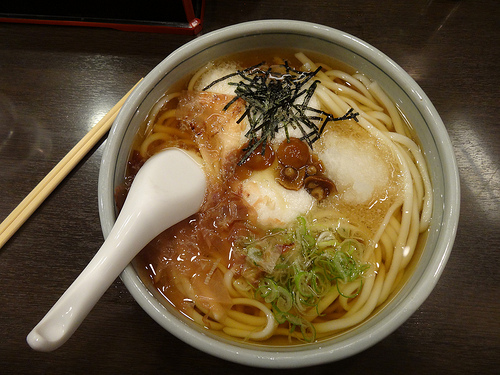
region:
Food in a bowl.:
[77, 21, 468, 371]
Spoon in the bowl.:
[41, 113, 276, 358]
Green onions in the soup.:
[215, 139, 405, 334]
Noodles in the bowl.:
[240, 57, 440, 274]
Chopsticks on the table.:
[22, 71, 212, 275]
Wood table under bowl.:
[39, 52, 432, 370]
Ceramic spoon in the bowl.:
[16, 110, 366, 371]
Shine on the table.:
[54, 58, 164, 189]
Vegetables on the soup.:
[200, 57, 365, 194]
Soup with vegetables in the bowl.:
[75, 57, 475, 302]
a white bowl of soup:
[84, 13, 479, 372]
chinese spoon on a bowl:
[9, 130, 214, 357]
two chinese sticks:
[10, 55, 140, 251]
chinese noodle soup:
[115, 47, 435, 340]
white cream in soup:
[232, 169, 308, 230]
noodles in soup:
[328, 65, 430, 280]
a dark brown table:
[0, 0, 499, 374]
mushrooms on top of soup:
[230, 124, 336, 209]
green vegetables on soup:
[211, 205, 374, 332]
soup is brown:
[111, 45, 439, 350]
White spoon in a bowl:
[128, 138, 222, 235]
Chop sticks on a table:
[1, 77, 131, 252]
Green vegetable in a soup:
[251, 233, 359, 316]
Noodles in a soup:
[373, 209, 425, 291]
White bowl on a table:
[98, 25, 457, 370]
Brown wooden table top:
[428, 310, 497, 374]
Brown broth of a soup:
[240, 47, 290, 67]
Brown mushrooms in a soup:
[276, 135, 311, 165]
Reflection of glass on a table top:
[3, 80, 60, 187]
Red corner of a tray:
[178, 0, 208, 32]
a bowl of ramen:
[187, 102, 418, 349]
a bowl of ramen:
[240, 234, 293, 328]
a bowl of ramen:
[233, 216, 265, 273]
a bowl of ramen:
[247, 184, 312, 311]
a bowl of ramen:
[244, 256, 308, 351]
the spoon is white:
[77, 130, 264, 370]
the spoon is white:
[28, 14, 250, 351]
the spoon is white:
[90, 133, 219, 262]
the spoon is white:
[96, 161, 205, 365]